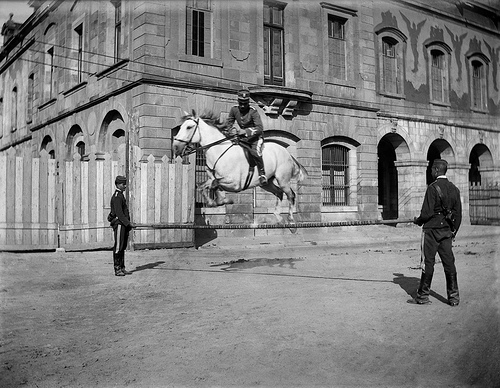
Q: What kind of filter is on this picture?
A: Black and white.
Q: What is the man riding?
A: Horse.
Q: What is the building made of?
A: Brick.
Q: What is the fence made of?
A: Wood.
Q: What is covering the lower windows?
A: Bars.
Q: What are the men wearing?
A: Uniforms.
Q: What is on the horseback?
A: Saddle and rider.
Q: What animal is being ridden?
A: Horse.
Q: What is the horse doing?
A: Jumping.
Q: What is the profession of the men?
A: Soldiers.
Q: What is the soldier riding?
A: Horse.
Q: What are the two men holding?
A: A pole.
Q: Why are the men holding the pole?
A: For the horse to jump over.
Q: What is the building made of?
A: Block.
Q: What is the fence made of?
A: Wood.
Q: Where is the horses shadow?
A: On the ground.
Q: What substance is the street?
A: Dirt.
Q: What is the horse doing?
A: Jumping through the air.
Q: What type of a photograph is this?
A: A black and white photograph.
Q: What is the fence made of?
A: Wood.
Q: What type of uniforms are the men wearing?
A: Soldiers' uniforms.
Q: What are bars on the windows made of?
A: Iron.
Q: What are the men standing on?
A: The ground.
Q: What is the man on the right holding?
A: A pole.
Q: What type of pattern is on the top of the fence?
A: Diamond shaped.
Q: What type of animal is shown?
A: Horse.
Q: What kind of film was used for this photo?
A: Black and white.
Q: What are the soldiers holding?
A: Pole.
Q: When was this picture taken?
A: Daytime.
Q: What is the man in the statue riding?
A: Horse.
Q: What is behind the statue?
A: A building.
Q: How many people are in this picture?
A: One.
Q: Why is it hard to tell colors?
A: Picture is black and white.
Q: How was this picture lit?
A: Natural light.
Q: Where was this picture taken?
A: Downtown.